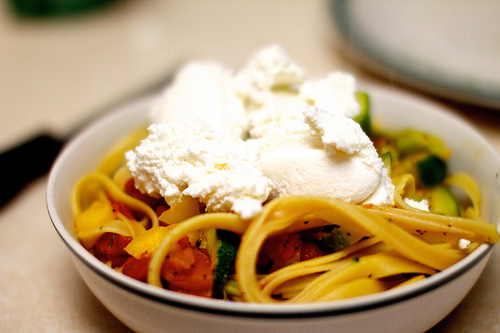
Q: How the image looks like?
A: Yummy.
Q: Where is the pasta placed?
A: In bowl.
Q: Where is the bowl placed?
A: On table.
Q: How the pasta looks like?
A: Yellow.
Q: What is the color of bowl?
A: White.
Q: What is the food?
A: Pasta.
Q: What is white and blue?
A: The bowl.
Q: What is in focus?
A: The food.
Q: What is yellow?
A: The pasta.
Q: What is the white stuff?
A: A topping.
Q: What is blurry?
A: The table.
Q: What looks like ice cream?
A: The topping.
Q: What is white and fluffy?
A: The topping.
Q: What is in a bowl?
A: Noodles.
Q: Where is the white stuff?
A: On top of the noodles.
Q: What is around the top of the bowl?
A: A stripe.